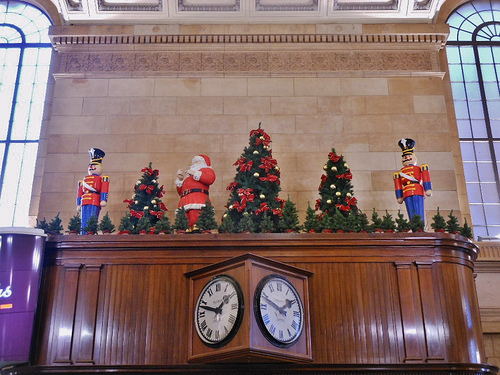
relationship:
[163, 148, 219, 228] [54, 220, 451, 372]
statue on shelf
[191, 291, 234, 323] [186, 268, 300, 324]
hand on clock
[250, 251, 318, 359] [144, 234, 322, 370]
clock on cube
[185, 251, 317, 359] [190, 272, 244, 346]
clock with face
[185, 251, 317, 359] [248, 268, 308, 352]
clock with face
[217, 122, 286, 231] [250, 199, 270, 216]
tree with bows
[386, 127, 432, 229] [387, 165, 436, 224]
soldier in uniform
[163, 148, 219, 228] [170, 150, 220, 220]
statue of santa clause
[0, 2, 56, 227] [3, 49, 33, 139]
window with sun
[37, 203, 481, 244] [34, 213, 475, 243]
row of trees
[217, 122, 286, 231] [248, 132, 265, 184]
tree with balls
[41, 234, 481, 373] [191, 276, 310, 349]
mantle with clocks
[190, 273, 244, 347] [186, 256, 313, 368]
clock facing directions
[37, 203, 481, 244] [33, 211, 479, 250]
row of trees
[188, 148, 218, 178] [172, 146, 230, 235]
head of figurine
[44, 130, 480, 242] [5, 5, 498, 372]
display in building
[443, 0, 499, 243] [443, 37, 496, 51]
window with trim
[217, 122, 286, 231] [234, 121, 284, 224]
tree with bows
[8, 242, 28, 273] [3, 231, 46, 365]
part of sign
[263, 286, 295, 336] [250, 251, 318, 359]
face of clock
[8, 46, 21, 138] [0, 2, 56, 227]
pane of window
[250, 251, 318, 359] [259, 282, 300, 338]
clock with face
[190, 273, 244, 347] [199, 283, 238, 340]
clock with face